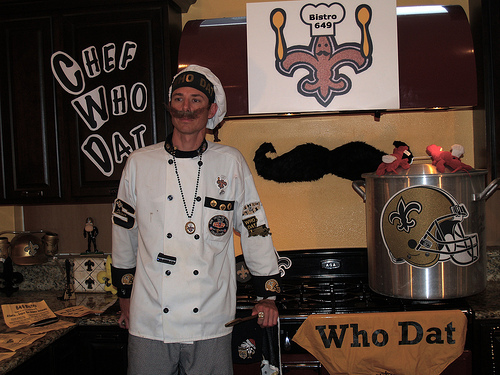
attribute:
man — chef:
[108, 65, 279, 375]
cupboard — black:
[2, 2, 167, 205]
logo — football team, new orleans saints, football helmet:
[378, 184, 482, 270]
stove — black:
[229, 245, 475, 375]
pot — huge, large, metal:
[344, 143, 498, 296]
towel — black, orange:
[296, 309, 469, 375]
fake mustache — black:
[163, 99, 214, 124]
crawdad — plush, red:
[421, 142, 478, 172]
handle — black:
[28, 316, 65, 327]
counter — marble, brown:
[0, 285, 135, 374]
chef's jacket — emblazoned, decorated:
[111, 149, 272, 337]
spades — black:
[81, 257, 99, 293]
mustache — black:
[250, 137, 423, 186]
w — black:
[69, 92, 113, 122]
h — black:
[112, 84, 129, 116]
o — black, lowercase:
[125, 81, 150, 113]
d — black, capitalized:
[74, 134, 117, 173]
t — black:
[129, 123, 148, 159]